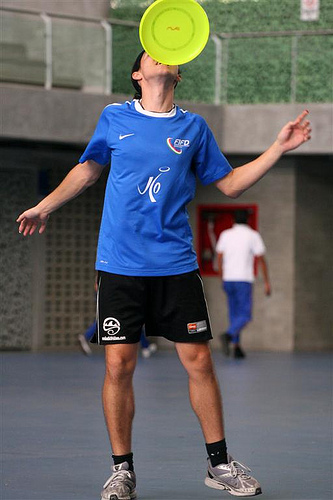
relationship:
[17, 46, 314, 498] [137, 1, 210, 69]
boy biting on a frisbee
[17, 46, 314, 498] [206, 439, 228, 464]
boy wearing black sock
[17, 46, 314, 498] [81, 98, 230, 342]
boy wearing uniform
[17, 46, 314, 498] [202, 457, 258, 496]
boy wearing sneaker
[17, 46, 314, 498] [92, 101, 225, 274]
boy wearing a blue shirt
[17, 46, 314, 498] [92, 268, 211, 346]
boy wearing black shorts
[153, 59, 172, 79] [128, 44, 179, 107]
chin on a mans head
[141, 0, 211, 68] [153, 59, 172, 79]
frisbee on a chin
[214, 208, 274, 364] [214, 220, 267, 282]
man wearing shirt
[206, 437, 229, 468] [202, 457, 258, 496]
black sock protruding from sneaker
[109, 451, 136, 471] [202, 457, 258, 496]
sock protruding from sneaker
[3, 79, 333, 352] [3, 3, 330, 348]
distance in distance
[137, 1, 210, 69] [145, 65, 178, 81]
frisbee on chin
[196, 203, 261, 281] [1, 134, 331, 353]
case on wall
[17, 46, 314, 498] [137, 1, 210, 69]
boy touching frisbee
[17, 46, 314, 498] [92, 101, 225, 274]
boy wearing blue shirt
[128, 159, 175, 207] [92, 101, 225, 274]
design on blue shirt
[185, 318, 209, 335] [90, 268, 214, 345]
tag on black shorts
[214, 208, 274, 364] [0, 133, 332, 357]
man in background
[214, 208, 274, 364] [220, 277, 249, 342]
man wearing blue pants